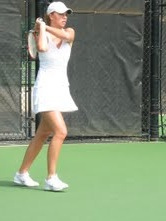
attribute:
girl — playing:
[13, 0, 80, 193]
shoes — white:
[12, 170, 70, 191]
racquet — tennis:
[27, 26, 39, 60]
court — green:
[0, 142, 165, 221]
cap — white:
[46, 1, 74, 16]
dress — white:
[32, 30, 79, 116]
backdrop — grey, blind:
[65, 0, 145, 138]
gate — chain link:
[1, 0, 33, 142]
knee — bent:
[54, 127, 69, 140]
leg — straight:
[17, 112, 50, 175]